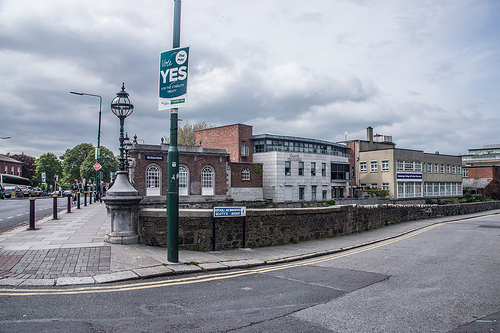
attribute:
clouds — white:
[261, 49, 421, 140]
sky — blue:
[217, 8, 489, 145]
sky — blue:
[0, 2, 498, 183]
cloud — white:
[6, 12, 228, 82]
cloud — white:
[161, 71, 373, 126]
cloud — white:
[224, 1, 498, 151]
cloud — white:
[3, 77, 103, 143]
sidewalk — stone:
[32, 227, 58, 274]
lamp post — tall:
[84, 90, 106, 190]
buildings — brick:
[133, 112, 496, 204]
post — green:
[136, 34, 208, 279]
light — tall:
[58, 77, 110, 219]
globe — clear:
[111, 92, 134, 119]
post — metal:
[110, 84, 130, 171]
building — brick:
[253, 132, 352, 210]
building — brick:
[352, 139, 468, 204]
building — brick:
[122, 130, 262, 216]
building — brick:
[463, 150, 496, 199]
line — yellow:
[311, 250, 338, 270]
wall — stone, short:
[128, 195, 492, 246]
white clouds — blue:
[245, 32, 403, 125]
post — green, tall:
[166, 0, 179, 263]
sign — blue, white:
[157, 46, 197, 116]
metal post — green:
[158, 121, 186, 268]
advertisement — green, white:
[157, 46, 192, 109]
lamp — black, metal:
[110, 92, 132, 120]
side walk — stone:
[18, 192, 107, 278]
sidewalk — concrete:
[105, 204, 497, 281]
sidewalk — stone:
[2, 198, 116, 288]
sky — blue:
[249, 15, 374, 107]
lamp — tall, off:
[69, 87, 105, 156]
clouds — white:
[2, 7, 498, 159]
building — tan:
[337, 125, 462, 198]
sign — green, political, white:
[157, 47, 189, 112]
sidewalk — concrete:
[3, 187, 118, 289]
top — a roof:
[255, 132, 355, 154]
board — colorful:
[210, 201, 248, 217]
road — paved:
[0, 194, 91, 230]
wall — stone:
[114, 203, 496, 256]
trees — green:
[31, 140, 116, 189]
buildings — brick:
[116, 118, 498, 235]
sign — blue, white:
[393, 172, 425, 182]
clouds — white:
[15, 0, 392, 144]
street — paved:
[4, 210, 497, 331]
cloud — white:
[220, 26, 271, 89]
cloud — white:
[335, 68, 388, 114]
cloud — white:
[78, 13, 140, 70]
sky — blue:
[4, 6, 498, 155]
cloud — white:
[416, 43, 440, 84]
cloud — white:
[375, 25, 426, 65]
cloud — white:
[375, 67, 437, 116]